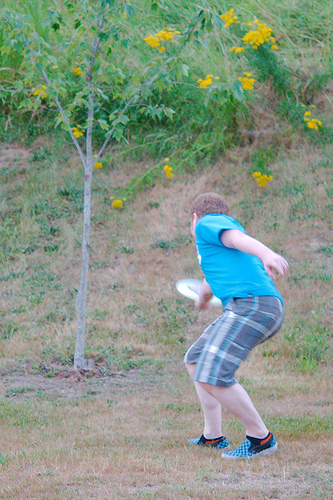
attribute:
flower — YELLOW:
[269, 30, 279, 49]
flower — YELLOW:
[69, 66, 82, 77]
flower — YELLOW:
[236, 74, 257, 95]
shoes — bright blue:
[184, 432, 279, 460]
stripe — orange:
[257, 434, 271, 443]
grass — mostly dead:
[22, 428, 175, 495]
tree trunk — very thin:
[69, 260, 90, 370]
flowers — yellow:
[140, 7, 279, 96]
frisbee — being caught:
[174, 275, 221, 308]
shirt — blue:
[194, 212, 267, 299]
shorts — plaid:
[182, 295, 284, 388]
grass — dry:
[33, 431, 174, 493]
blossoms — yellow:
[141, 6, 283, 95]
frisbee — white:
[173, 276, 225, 308]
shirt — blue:
[190, 210, 284, 302]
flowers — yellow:
[250, 168, 273, 187]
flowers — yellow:
[301, 100, 325, 135]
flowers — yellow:
[236, 69, 260, 94]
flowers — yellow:
[195, 70, 222, 89]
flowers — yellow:
[142, 21, 185, 54]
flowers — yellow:
[108, 189, 129, 210]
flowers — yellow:
[163, 149, 177, 181]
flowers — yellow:
[253, 169, 274, 192]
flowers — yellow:
[298, 109, 327, 132]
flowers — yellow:
[218, 2, 237, 29]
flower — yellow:
[247, 168, 276, 189]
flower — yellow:
[300, 107, 321, 134]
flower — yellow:
[242, 16, 278, 49]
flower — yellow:
[196, 71, 221, 89]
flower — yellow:
[107, 190, 128, 209]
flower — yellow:
[299, 107, 326, 133]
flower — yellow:
[160, 154, 176, 181]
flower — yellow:
[301, 107, 325, 137]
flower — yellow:
[242, 16, 285, 54]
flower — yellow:
[234, 64, 258, 94]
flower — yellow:
[71, 120, 86, 141]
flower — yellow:
[245, 24, 269, 50]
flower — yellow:
[217, 10, 235, 22]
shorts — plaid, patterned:
[189, 288, 304, 387]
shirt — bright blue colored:
[185, 214, 300, 315]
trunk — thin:
[74, 161, 95, 376]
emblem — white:
[187, 242, 209, 264]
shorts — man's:
[192, 296, 293, 391]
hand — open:
[266, 259, 295, 277]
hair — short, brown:
[188, 187, 231, 221]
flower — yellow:
[109, 193, 123, 212]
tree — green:
[5, 80, 150, 389]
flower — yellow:
[152, 159, 188, 183]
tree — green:
[3, 3, 182, 392]